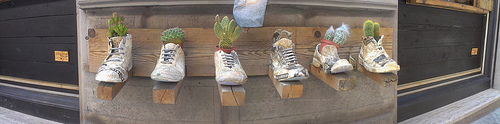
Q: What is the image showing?
A: It is showing a display.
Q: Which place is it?
A: It is a display.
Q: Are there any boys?
A: No, there are no boys.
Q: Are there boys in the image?
A: No, there are no boys.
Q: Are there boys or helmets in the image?
A: No, there are no boys or helmets.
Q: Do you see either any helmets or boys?
A: No, there are no boys or helmets.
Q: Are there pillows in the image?
A: No, there are no pillows.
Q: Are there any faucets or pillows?
A: No, there are no pillows or faucets.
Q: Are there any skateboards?
A: No, there are no skateboards.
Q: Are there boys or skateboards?
A: No, there are no skateboards or boys.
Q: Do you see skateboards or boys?
A: No, there are no skateboards or boys.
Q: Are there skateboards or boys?
A: No, there are no skateboards or boys.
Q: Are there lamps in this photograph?
A: No, there are no lamps.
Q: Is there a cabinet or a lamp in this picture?
A: No, there are no lamps or cabinets.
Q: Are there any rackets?
A: No, there are no rackets.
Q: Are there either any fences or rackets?
A: No, there are no rackets or fences.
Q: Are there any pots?
A: Yes, there is a pot.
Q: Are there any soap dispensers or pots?
A: Yes, there is a pot.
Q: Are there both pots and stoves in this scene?
A: No, there is a pot but no stoves.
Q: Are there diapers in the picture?
A: No, there are no diapers.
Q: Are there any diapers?
A: No, there are no diapers.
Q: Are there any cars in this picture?
A: No, there are no cars.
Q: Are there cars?
A: No, there are no cars.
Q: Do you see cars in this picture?
A: No, there are no cars.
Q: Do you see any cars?
A: No, there are no cars.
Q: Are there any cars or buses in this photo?
A: No, there are no cars or buses.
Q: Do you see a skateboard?
A: No, there are no skateboards.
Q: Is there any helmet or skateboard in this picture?
A: No, there are no skateboards or helmets.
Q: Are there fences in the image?
A: No, there are no fences.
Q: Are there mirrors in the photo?
A: No, there are no mirrors.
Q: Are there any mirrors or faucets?
A: No, there are no mirrors or faucets.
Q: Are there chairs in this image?
A: No, there are no chairs.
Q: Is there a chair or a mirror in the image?
A: No, there are no chairs or mirrors.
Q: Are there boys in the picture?
A: No, there are no boys.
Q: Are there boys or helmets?
A: No, there are no boys or helmets.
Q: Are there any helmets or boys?
A: No, there are no boys or helmets.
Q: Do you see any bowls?
A: No, there are no bowls.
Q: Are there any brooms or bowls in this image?
A: No, there are no bowls or brooms.